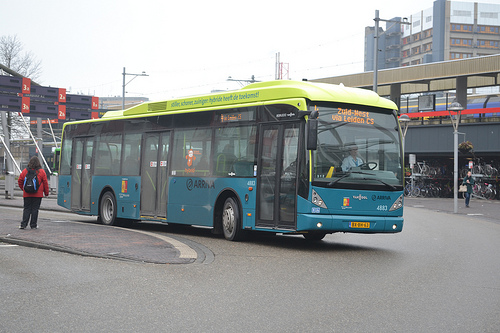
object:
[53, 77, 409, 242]
bus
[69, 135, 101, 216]
door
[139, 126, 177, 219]
door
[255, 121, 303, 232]
door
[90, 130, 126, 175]
window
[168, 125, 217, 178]
window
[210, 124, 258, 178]
window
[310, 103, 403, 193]
windshield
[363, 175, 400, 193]
wiper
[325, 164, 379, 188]
wiper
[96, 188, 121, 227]
tire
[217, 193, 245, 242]
tire